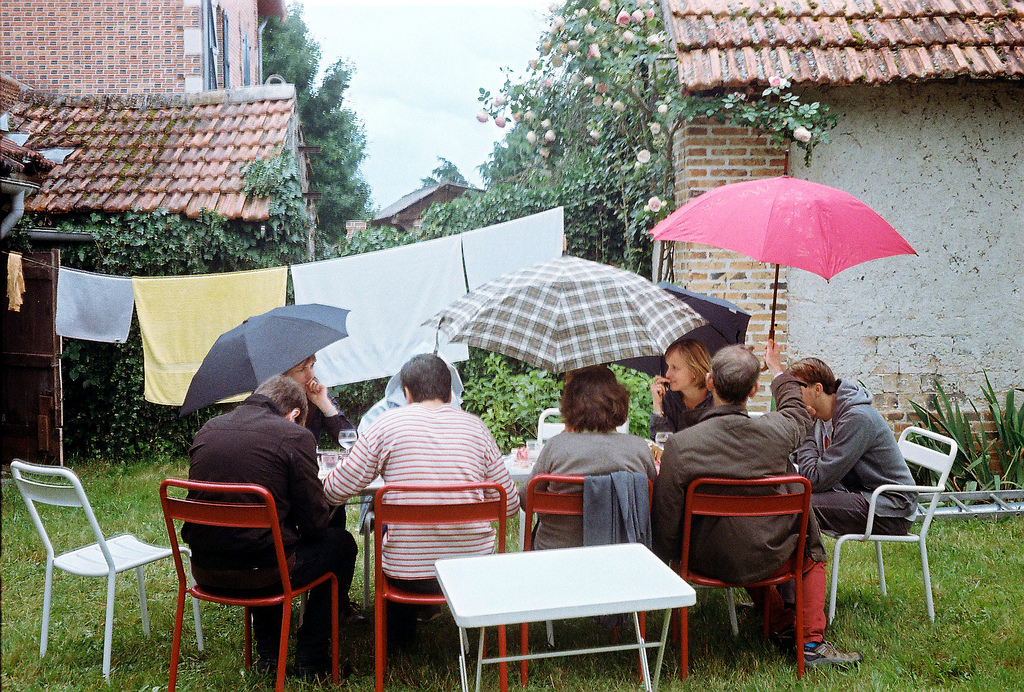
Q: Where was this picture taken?
A: Next to people.